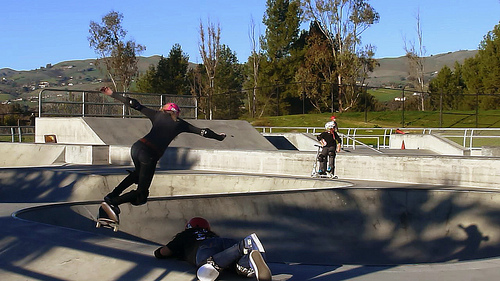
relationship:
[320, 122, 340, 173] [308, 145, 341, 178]
child riding scooter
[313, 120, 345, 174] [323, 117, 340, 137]
child has head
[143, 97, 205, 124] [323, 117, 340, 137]
helmet on head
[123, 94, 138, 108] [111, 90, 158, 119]
elbow pad on arm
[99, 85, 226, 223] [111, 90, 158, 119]
girl has arm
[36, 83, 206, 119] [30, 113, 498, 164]
rail on top of ramp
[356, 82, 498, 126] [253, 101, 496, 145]
fence on grass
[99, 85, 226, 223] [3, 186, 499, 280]
girl skateboarding on ramp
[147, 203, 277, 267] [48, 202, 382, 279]
person laying on ramp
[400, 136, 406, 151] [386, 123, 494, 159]
cone beside ramp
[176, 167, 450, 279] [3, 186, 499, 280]
shadows on ramp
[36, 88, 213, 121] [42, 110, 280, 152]
rail on ramp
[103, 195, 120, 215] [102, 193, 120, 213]
sneaker on foot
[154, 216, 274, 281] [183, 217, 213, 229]
person wearing helmet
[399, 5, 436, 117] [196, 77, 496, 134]
tree behind fence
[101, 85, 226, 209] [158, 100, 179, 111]
girl wears helmet